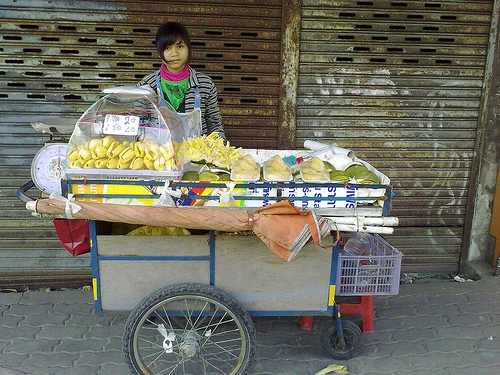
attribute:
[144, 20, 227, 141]
woman — young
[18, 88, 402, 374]
food cart — mobile, small, blue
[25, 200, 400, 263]
umbrella — closed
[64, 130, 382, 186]
food — displayed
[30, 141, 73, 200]
scale — metal, white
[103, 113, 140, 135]
price tag — white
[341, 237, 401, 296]
basket — plastic, blue, purple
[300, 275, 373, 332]
stool — red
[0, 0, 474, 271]
wall — metal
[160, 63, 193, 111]
scarf — green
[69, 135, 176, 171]
bananas — yellow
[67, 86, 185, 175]
dome — plastic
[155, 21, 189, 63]
hair — black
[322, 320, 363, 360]
front wheel — small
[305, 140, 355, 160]
paper towel — roll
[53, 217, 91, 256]
bag — red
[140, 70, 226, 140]
shirt — striped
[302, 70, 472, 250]
painting — white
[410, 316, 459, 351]
stones — grey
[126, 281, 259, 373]
wheel — big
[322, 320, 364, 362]
wheel — small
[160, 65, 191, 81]
fabric — pink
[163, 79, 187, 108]
fabric — green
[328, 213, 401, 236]
pole — white